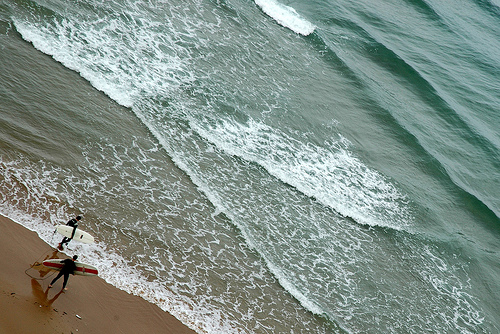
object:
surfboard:
[40, 258, 100, 275]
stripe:
[41, 262, 98, 276]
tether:
[50, 229, 56, 245]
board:
[50, 223, 95, 244]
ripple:
[0, 0, 499, 333]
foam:
[254, 0, 316, 39]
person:
[46, 253, 78, 292]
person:
[53, 215, 83, 251]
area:
[0, 215, 197, 334]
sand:
[0, 216, 196, 334]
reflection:
[30, 277, 54, 310]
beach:
[0, 203, 203, 334]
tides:
[0, 1, 498, 334]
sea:
[0, 0, 499, 332]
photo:
[0, 0, 499, 334]